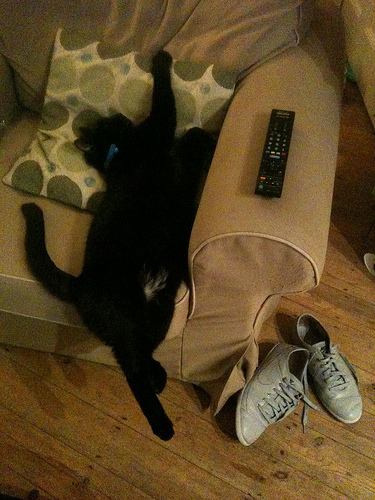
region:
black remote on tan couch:
[256, 103, 299, 200]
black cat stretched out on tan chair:
[15, 44, 227, 443]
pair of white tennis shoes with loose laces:
[234, 305, 367, 456]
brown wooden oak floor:
[5, 195, 370, 491]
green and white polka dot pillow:
[5, 29, 246, 205]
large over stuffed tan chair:
[1, 1, 372, 426]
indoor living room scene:
[6, 10, 366, 495]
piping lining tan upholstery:
[4, 229, 323, 331]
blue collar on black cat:
[98, 131, 133, 172]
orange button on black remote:
[259, 173, 267, 183]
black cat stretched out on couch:
[50, 36, 246, 440]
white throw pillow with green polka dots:
[8, 28, 239, 214]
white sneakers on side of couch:
[227, 309, 363, 452]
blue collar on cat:
[92, 138, 134, 187]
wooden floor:
[24, 386, 132, 487]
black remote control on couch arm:
[240, 87, 312, 204]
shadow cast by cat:
[13, 289, 103, 426]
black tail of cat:
[6, 186, 87, 305]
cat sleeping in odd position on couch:
[38, 52, 215, 457]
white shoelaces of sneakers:
[252, 375, 314, 436]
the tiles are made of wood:
[26, 439, 227, 490]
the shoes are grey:
[251, 345, 364, 430]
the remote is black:
[250, 98, 310, 211]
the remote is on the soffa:
[255, 105, 318, 217]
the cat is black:
[81, 126, 189, 384]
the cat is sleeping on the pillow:
[24, 119, 178, 398]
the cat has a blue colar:
[57, 49, 210, 230]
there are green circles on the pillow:
[67, 60, 129, 101]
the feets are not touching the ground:
[112, 372, 201, 443]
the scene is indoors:
[0, 6, 372, 499]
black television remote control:
[251, 106, 297, 199]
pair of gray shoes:
[234, 311, 363, 449]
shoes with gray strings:
[256, 376, 320, 424]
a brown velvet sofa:
[0, 0, 342, 417]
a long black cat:
[19, 46, 214, 444]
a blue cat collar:
[99, 140, 118, 173]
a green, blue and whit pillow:
[2, 28, 237, 214]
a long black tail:
[19, 200, 81, 305]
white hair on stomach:
[139, 265, 169, 300]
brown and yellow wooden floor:
[0, 53, 372, 497]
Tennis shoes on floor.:
[232, 313, 365, 452]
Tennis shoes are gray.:
[231, 309, 363, 453]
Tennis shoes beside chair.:
[222, 309, 364, 448]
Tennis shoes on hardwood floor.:
[224, 306, 371, 448]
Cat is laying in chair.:
[21, 46, 221, 442]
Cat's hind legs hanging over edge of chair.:
[16, 238, 220, 450]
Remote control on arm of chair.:
[234, 96, 306, 219]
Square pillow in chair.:
[3, 21, 246, 242]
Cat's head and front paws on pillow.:
[68, 49, 222, 218]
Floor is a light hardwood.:
[1, 78, 373, 499]